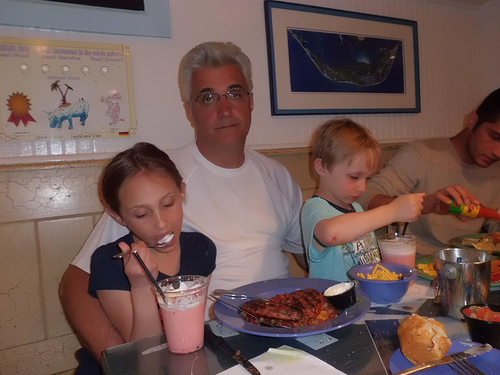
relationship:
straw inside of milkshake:
[130, 247, 169, 302] [155, 272, 211, 353]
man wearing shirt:
[58, 41, 310, 375] [173, 146, 293, 276]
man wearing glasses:
[182, 44, 269, 154] [184, 80, 249, 103]